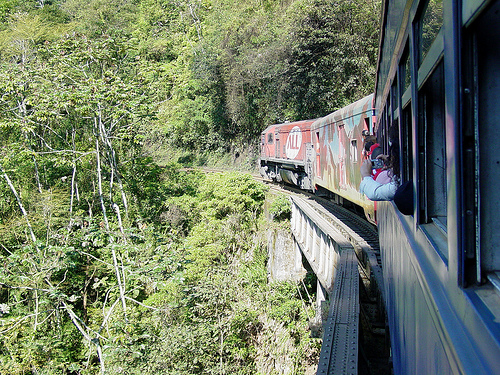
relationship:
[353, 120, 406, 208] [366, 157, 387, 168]
person taking picture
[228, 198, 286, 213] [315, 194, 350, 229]
foliage on track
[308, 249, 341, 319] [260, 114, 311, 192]
bridge of train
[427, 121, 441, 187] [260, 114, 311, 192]
window on train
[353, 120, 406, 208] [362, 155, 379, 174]
person holding camera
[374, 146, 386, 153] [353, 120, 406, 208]
cap on person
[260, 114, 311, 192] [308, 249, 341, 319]
train on bridge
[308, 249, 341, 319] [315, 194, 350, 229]
bridge has track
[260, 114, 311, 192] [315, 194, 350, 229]
train on track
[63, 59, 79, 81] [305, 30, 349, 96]
branch of tree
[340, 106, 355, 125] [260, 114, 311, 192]
painting on train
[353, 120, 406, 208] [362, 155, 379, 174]
person has camera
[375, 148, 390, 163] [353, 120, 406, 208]
head of person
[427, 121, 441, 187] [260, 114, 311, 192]
window of train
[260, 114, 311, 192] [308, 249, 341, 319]
train passing bridge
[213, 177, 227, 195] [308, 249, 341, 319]
fence on bridge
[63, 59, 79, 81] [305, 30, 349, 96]
branch on tree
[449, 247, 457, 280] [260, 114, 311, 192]
door on train